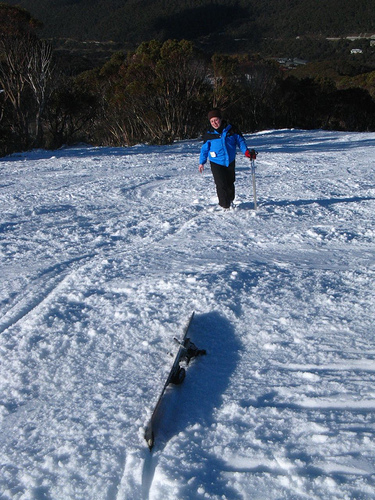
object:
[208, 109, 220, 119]
hat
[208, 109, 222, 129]
head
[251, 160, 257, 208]
poles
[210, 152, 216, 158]
paper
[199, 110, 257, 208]
person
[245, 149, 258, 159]
glove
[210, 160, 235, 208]
pants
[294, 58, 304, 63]
roof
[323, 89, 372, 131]
tree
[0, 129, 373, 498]
snow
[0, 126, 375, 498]
ground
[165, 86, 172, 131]
branches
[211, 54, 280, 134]
tree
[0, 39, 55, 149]
tree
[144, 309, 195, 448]
board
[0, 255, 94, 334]
tracks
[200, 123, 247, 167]
coat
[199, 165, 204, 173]
hand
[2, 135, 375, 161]
shadow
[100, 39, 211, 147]
tree